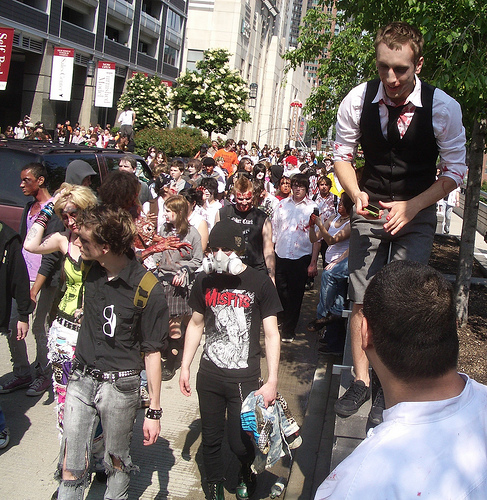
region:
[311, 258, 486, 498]
A brown haired man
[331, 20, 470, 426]
A man in a vest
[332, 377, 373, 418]
A black right shoe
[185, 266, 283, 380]
A black Misfits shirt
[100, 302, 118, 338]
A pair of white sunglasses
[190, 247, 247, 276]
A white face mask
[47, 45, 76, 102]
A red and white hanging banner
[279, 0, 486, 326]
A planted tree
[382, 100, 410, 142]
A black neck tie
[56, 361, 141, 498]
A pair of ripped jeans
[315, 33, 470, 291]
this is a man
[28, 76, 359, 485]
a large group of people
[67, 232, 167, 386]
man wearing a black shirt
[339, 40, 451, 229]
man wearing a black vest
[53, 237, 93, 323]
woman wearing a green shirt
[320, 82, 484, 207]
man wearing a white shirt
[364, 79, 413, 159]
man wearing a tie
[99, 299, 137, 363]
a white pair of sunlgasses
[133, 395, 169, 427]
a black wrist bracelet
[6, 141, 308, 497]
people walking on the street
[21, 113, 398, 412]
people walking down a street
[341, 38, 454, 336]
a person standing on a wall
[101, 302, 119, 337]
white sunglasses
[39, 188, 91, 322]
a person in a green shirt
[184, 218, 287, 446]
a person wearing a mask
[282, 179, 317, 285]
a person in a white shirt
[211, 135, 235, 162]
a person in an orange shirt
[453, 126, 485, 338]
a tree behind the man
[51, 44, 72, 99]
a sign hanging from the building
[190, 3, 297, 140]
a white building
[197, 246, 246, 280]
a fume protection mask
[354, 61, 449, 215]
a black vest on a man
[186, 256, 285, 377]
a black, white, and red misfits shirt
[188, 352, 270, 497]
tight black jeans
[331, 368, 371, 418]
a black sneaker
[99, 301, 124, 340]
white sunglasses on a man's shirt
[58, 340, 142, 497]
torn grey jeans on a man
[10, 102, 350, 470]
a crown of people dressed weird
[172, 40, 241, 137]
a tree with blooming white flowers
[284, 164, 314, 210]
andy milianakas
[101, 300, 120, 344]
white framed glasses in pocket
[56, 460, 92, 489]
jeans are ripped in the knees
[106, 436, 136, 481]
jeans are ripped in the knees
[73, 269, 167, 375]
person wearing a black shirt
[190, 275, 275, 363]
person wearing a black shirt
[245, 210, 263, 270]
person wearing a black shirt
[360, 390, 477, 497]
person wearing a white shirt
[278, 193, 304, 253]
person wearing a white shirt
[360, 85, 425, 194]
person wearing a black vest